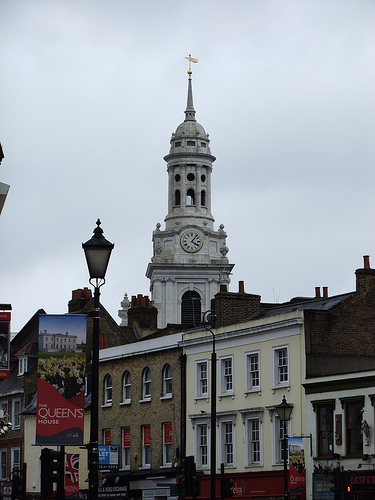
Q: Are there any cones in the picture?
A: No, there are no cones.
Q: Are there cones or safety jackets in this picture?
A: No, there are no cones or safety jackets.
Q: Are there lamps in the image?
A: Yes, there is a lamp.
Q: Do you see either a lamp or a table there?
A: Yes, there is a lamp.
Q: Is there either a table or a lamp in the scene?
A: Yes, there is a lamp.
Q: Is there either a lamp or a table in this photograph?
A: Yes, there is a lamp.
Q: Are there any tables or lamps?
A: Yes, there is a lamp.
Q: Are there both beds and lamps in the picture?
A: No, there is a lamp but no beds.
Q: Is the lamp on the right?
A: Yes, the lamp is on the right of the image.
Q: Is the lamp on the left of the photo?
A: No, the lamp is on the right of the image.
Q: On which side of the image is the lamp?
A: The lamp is on the right of the image.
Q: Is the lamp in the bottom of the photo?
A: Yes, the lamp is in the bottom of the image.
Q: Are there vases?
A: No, there are no vases.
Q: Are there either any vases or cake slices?
A: No, there are no vases or cake slices.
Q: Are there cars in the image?
A: No, there are no cars.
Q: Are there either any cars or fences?
A: No, there are no cars or fences.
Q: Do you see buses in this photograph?
A: No, there are no buses.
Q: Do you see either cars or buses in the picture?
A: No, there are no buses or cars.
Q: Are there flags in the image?
A: Yes, there is a flag.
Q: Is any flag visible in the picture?
A: Yes, there is a flag.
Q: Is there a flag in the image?
A: Yes, there is a flag.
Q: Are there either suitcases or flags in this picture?
A: Yes, there is a flag.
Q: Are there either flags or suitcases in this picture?
A: Yes, there is a flag.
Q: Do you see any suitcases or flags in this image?
A: Yes, there is a flag.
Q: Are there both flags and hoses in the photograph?
A: No, there is a flag but no hoses.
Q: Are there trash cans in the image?
A: No, there are no trash cans.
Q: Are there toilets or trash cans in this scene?
A: No, there are no trash cans or toilets.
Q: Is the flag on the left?
A: Yes, the flag is on the left of the image.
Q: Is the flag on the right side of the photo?
A: No, the flag is on the left of the image.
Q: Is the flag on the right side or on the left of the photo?
A: The flag is on the left of the image.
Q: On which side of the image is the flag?
A: The flag is on the left of the image.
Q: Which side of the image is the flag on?
A: The flag is on the left of the image.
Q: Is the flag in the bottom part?
A: Yes, the flag is in the bottom of the image.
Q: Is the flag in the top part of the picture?
A: No, the flag is in the bottom of the image.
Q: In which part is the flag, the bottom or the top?
A: The flag is in the bottom of the image.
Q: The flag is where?
A: The flag is on the road.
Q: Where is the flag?
A: The flag is on the road.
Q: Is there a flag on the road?
A: Yes, there is a flag on the road.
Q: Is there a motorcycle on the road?
A: No, there is a flag on the road.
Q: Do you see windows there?
A: Yes, there are windows.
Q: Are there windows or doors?
A: Yes, there are windows.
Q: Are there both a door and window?
A: No, there are windows but no doors.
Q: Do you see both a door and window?
A: No, there are windows but no doors.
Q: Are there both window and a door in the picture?
A: No, there are windows but no doors.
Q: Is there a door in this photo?
A: No, there are no doors.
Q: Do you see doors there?
A: No, there are no doors.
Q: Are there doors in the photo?
A: No, there are no doors.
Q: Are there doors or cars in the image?
A: No, there are no doors or cars.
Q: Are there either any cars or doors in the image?
A: No, there are no doors or cars.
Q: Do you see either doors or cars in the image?
A: No, there are no doors or cars.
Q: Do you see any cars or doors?
A: No, there are no doors or cars.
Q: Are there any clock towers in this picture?
A: Yes, there is a clock tower.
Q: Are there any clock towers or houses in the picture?
A: Yes, there is a clock tower.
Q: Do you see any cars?
A: No, there are no cars.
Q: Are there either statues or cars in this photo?
A: No, there are no cars or statues.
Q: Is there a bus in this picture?
A: No, there are no buses.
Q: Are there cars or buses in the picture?
A: No, there are no buses or cars.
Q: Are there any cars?
A: No, there are no cars.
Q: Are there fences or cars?
A: No, there are no cars or fences.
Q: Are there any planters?
A: No, there are no planters.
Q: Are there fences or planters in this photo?
A: No, there are no planters or fences.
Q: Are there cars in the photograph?
A: No, there are no cars.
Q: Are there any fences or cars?
A: No, there are no cars or fences.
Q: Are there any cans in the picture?
A: No, there are no cans.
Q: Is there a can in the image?
A: No, there are no cans.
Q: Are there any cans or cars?
A: No, there are no cans or cars.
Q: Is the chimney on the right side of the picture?
A: Yes, the chimney is on the right of the image.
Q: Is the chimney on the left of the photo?
A: No, the chimney is on the right of the image.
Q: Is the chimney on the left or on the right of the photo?
A: The chimney is on the right of the image.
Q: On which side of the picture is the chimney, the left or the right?
A: The chimney is on the right of the image.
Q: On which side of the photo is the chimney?
A: The chimney is on the right of the image.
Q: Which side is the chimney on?
A: The chimney is on the right of the image.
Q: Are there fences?
A: No, there are no fences.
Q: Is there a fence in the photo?
A: No, there are no fences.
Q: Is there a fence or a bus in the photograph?
A: No, there are no fences or buses.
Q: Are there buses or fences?
A: No, there are no fences or buses.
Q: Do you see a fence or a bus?
A: No, there are no fences or buses.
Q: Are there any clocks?
A: Yes, there is a clock.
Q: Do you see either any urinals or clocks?
A: Yes, there is a clock.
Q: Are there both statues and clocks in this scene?
A: No, there is a clock but no statues.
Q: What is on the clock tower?
A: The clock is on the clock tower.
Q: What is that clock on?
A: The clock is on the clock tower.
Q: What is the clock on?
A: The clock is on the clock tower.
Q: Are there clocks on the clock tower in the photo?
A: Yes, there is a clock on the clock tower.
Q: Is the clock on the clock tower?
A: Yes, the clock is on the clock tower.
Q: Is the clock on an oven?
A: No, the clock is on the clock tower.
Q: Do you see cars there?
A: No, there are no cars.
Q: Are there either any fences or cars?
A: No, there are no cars or fences.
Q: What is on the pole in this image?
A: The sign is on the pole.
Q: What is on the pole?
A: The sign is on the pole.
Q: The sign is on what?
A: The sign is on the pole.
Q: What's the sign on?
A: The sign is on the pole.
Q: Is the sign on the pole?
A: Yes, the sign is on the pole.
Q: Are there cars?
A: No, there are no cars.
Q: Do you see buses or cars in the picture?
A: No, there are no cars or buses.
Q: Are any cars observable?
A: No, there are no cars.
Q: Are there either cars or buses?
A: No, there are no cars or buses.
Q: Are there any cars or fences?
A: No, there are no cars or fences.